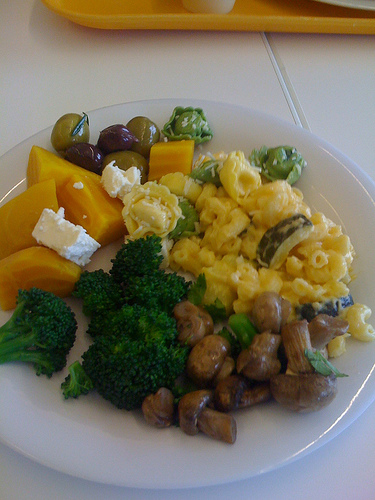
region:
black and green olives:
[59, 98, 152, 171]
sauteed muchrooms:
[148, 308, 322, 430]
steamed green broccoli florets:
[1, 250, 184, 402]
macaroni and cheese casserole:
[211, 168, 352, 304]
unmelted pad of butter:
[29, 200, 101, 261]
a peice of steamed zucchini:
[255, 203, 311, 275]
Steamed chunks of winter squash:
[258, 37, 305, 130]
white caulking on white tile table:
[20, 21, 374, 106]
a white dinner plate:
[17, 371, 373, 485]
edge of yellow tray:
[40, 2, 372, 32]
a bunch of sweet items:
[0, 101, 372, 372]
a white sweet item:
[28, 211, 94, 261]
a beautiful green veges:
[48, 293, 163, 386]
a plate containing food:
[0, 115, 373, 476]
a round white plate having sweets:
[1, 43, 334, 459]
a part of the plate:
[60, 438, 353, 495]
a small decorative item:
[251, 213, 321, 267]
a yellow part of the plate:
[98, 2, 371, 49]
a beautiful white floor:
[36, 45, 372, 119]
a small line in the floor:
[267, 50, 316, 136]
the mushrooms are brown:
[137, 290, 353, 443]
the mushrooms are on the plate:
[138, 290, 351, 444]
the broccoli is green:
[0, 229, 203, 409]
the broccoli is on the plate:
[0, 230, 207, 413]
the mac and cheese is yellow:
[111, 143, 372, 356]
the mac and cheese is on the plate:
[117, 146, 369, 356]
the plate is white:
[0, 92, 373, 490]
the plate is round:
[0, 83, 372, 491]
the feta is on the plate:
[28, 158, 151, 266]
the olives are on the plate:
[47, 107, 161, 185]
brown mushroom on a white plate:
[177, 391, 241, 443]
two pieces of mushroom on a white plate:
[144, 390, 237, 446]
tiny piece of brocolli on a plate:
[58, 359, 92, 399]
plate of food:
[0, 94, 373, 497]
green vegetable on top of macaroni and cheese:
[256, 211, 314, 265]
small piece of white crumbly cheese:
[29, 206, 102, 266]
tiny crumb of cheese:
[72, 180, 83, 188]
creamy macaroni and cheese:
[171, 152, 355, 307]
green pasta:
[159, 104, 215, 139]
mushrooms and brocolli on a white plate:
[60, 291, 339, 445]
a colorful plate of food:
[1, 103, 371, 467]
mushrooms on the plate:
[132, 291, 351, 444]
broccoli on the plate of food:
[0, 231, 212, 412]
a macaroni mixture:
[171, 154, 374, 341]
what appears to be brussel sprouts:
[158, 105, 316, 238]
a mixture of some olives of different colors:
[54, 107, 168, 187]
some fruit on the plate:
[1, 143, 128, 312]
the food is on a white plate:
[4, 94, 372, 483]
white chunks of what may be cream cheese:
[30, 155, 146, 272]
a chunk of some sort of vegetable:
[251, 211, 318, 273]